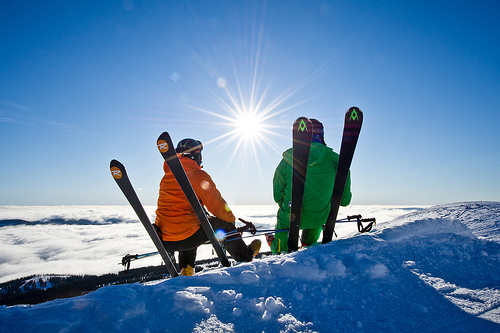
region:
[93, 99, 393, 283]
two skiiers taking a break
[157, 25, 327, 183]
bright winter sun a blue sky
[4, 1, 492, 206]
crystal clear blue sky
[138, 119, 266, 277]
skiier is wearing an orange parka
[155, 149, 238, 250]
orange parka worn by skiier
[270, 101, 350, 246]
skiier is wearing a green parka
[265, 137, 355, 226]
green parka worn by skiier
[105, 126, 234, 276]
black skis with orange decal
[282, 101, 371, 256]
black skis with green decal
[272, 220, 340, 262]
green pants worn by skiier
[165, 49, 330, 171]
The sun is in the sky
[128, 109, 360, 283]
Two people are sitting down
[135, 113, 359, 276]
Two people in the foreground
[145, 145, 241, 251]
Person is wearing an orange coat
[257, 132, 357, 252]
Person is wearing a green coat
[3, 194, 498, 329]
Snow is covering the ground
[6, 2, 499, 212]
The sky is clear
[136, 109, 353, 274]
Person is turned away from the camera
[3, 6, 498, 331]
Photo was taken outdoors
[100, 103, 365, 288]
Photo was taken in the daytime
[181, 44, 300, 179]
The bright sun against a vibrant blue sky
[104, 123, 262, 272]
A skiier wearing orange taking a break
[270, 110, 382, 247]
A skiier wearing green resting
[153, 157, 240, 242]
A bright orange hoodie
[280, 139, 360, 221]
A bright green hoodie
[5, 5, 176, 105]
A portion of vibrant blue sky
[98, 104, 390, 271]
A pair of skiiers taking a rest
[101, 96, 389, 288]
A couple of skiiers taking a rest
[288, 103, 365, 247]
Black skiis with green decals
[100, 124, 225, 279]
Black skiis with orange decals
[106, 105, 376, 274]
two people with skis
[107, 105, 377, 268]
two people with skis on the top of a mountain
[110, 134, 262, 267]
a person in an orange jacket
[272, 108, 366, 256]
a person in a green jacket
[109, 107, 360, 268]
people on the top of a mountain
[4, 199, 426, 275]
clouds below the mountain top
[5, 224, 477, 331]
snow on the top of a mountain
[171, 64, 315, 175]
bright sun shining in the sky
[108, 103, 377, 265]
tow people enjoying the view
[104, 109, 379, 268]
two people about to go skiing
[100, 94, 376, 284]
the people sitting on the hill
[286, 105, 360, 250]
the black skies behind the man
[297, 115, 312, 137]
the green logo on the tip of the ski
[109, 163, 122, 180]
the orange round logo on the ski tip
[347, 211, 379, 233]
the handle of the ski poles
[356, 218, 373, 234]
the bands on the ski poles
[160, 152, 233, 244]
the oprange jacket on the skier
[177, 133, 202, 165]
the black helemet on the skier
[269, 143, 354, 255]
the green suit on the skier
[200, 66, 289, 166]
the blur from the shining sun